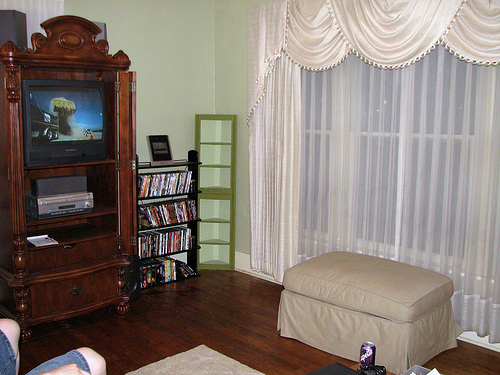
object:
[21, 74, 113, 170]
television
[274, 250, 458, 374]
ottoman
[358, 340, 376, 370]
soda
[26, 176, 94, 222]
sound system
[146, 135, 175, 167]
picture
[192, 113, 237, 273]
rack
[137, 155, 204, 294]
dvd rack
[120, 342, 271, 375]
rug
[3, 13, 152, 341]
entertainment center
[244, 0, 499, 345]
curtains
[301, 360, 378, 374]
table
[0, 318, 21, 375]
leg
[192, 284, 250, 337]
floor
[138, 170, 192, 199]
dvds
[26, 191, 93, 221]
dvd player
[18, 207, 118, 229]
shelf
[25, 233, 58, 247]
booklet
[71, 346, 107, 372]
knees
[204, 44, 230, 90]
corner